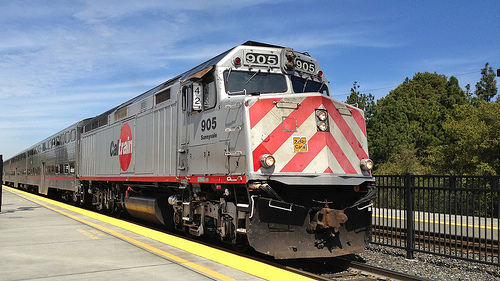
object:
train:
[0, 30, 373, 274]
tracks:
[286, 265, 344, 281]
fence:
[380, 168, 499, 268]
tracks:
[339, 257, 434, 281]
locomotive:
[0, 41, 374, 256]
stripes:
[252, 94, 326, 174]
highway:
[368, 203, 498, 255]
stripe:
[3, 185, 326, 280]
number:
[194, 97, 200, 104]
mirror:
[204, 81, 217, 109]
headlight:
[319, 121, 329, 131]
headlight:
[265, 156, 275, 166]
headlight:
[367, 160, 374, 168]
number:
[246, 54, 276, 64]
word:
[118, 137, 134, 155]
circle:
[117, 124, 134, 171]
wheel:
[218, 214, 235, 245]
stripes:
[251, 97, 286, 129]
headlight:
[318, 121, 328, 132]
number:
[194, 87, 200, 94]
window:
[56, 136, 60, 145]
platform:
[2, 181, 335, 278]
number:
[200, 116, 217, 132]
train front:
[227, 38, 375, 261]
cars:
[2, 119, 85, 200]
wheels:
[229, 214, 250, 252]